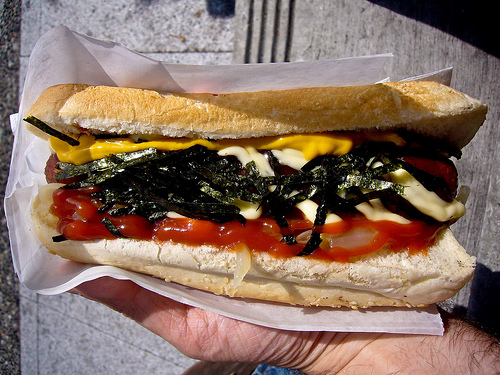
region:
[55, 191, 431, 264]
The ketchp on the sandwich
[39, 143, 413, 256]
the nori on the sandwich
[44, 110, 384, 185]
the mustard on the sandwich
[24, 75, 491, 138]
the bead on the sandwich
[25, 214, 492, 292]
the bottom bread on the sandwich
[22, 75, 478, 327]
a full sandwich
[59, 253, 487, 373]
a human hand and arm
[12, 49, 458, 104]
the top tissue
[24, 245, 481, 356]
the bottom tissue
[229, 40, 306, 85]
three lines on the brick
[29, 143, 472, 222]
a hot dog on a bun.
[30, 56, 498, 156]
a brown bun.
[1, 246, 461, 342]
a white wrapper under a hot dog bun.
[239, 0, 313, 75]
a dork under a hot dog.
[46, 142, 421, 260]
a topping on a hot dog.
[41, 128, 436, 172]
mustard on a hot dog.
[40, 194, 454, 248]
ketchup on a hot dog.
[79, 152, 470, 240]
mayo on a hot dog.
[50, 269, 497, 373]
a hand under a hot dog.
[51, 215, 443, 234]
ketchup near a bun.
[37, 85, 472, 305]
A large sandwich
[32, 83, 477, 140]
A slice of white bread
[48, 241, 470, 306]
A slice of white bread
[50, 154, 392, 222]
a handful of seaweed on a sandwich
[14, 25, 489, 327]
A sandwich in wrapping paper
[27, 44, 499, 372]
A hand holding a sandwich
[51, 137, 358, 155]
A slice of melted cheese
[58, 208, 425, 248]
Roasted red peppers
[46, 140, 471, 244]
The filling of a sandwich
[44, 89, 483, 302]
A sandwich filled with fresh ingredients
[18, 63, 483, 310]
this sandwich is not small, & if there's meat, it's hidden ;-}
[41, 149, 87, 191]
i think this is the end of the meat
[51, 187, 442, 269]
ketchup, loads of it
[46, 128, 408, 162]
bright yellow mustard, ibid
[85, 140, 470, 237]
mayonnaise or some equally fatty white goup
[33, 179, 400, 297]
onions, chunked, one falling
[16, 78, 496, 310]
long bun, sesame seeds on the bottom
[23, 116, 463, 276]
i think it's seaweed, nori, but i dont know why it's there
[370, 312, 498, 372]
lots of hair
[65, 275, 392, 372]
lots of little wrinkles before you get to the big ones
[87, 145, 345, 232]
seaweeds in the bun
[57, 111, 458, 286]
seaweeds in the bun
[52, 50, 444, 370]
person holding a hotdog sandwich